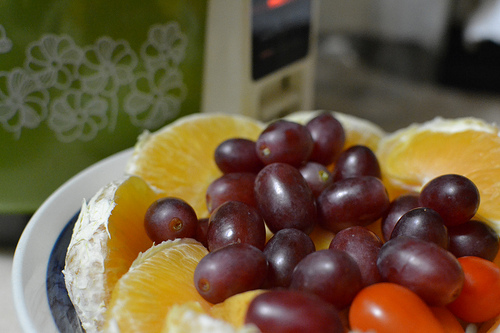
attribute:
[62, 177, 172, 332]
orange slice — peeled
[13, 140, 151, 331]
plate — white, designed, blue, fruit, full, assorted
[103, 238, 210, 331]
orange slice — peeled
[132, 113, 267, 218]
orange slice — white, peeled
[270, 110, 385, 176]
orange slice — peeled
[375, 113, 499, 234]
orange slice — peeled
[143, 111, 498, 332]
grapes — red, small, purple, large, fresh, stemless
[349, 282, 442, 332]
tomato — red, tiny, small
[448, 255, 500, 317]
tomato — red, tiny, small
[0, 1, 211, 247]
object — green, white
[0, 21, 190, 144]
flowers — floral design, white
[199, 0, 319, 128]
appliance — blurry, small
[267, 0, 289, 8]
light — red